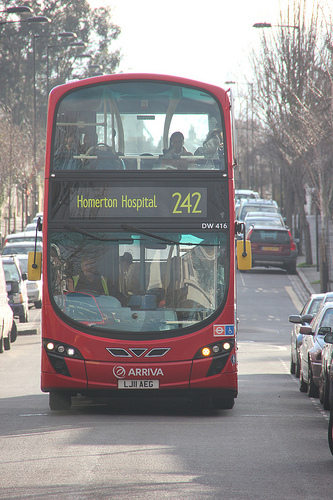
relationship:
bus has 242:
[23, 73, 252, 410] [171, 190, 201, 213]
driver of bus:
[74, 251, 101, 288] [23, 73, 252, 410]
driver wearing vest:
[74, 251, 99, 283] [97, 272, 110, 296]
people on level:
[55, 113, 213, 301] [36, 72, 233, 177]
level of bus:
[36, 72, 233, 177] [23, 73, 252, 410]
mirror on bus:
[237, 236, 251, 269] [23, 73, 252, 410]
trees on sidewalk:
[236, 1, 332, 295] [285, 229, 332, 310]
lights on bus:
[192, 340, 230, 359] [23, 73, 252, 410]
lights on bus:
[40, 336, 83, 358] [23, 73, 252, 410]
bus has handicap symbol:
[23, 73, 252, 410] [225, 323, 235, 336]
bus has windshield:
[23, 73, 252, 410] [41, 219, 235, 342]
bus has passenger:
[23, 73, 252, 410] [58, 125, 85, 156]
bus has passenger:
[23, 73, 252, 410] [81, 126, 106, 152]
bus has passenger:
[23, 73, 252, 410] [156, 126, 197, 162]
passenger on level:
[58, 125, 85, 156] [36, 72, 233, 177]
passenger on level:
[81, 126, 106, 152] [36, 72, 233, 177]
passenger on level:
[156, 126, 197, 162] [36, 72, 233, 177]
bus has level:
[23, 73, 252, 410] [38, 219, 231, 353]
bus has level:
[23, 73, 252, 410] [50, 75, 231, 175]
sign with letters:
[69, 187, 208, 216] [75, 193, 160, 211]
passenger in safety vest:
[62, 251, 121, 298] [67, 271, 111, 295]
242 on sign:
[169, 188, 203, 217] [50, 174, 236, 221]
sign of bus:
[50, 174, 236, 221] [23, 73, 252, 410]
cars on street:
[297, 290, 333, 394] [3, 269, 330, 497]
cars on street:
[297, 301, 332, 394] [3, 269, 330, 497]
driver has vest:
[74, 251, 101, 288] [66, 271, 109, 295]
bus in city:
[23, 73, 252, 410] [1, 0, 332, 496]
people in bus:
[55, 113, 213, 301] [18, 65, 251, 432]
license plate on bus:
[115, 375, 160, 390] [24, 56, 277, 399]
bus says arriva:
[23, 73, 252, 410] [127, 365, 166, 379]